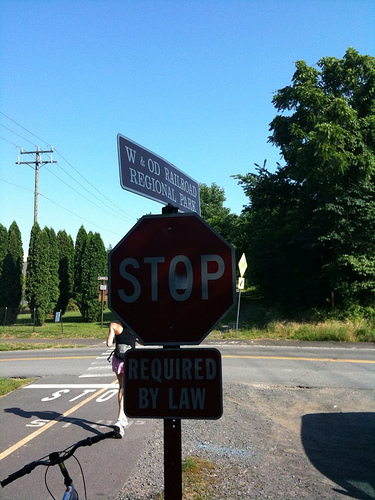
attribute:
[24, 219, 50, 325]
tree — in background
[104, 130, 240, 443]
sign — stop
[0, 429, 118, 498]
bike — blue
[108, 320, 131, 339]
top — black, tank top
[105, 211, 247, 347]
sign — red, white, stop sign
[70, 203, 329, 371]
sign — green, W & OD Railroad Regional Park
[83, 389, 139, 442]
shoe — athletic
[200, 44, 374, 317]
trees — leafy, green, on right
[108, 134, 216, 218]
rectangular sign — black, white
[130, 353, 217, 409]
writing — white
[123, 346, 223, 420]
sign — rectangular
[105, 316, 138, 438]
woman — jogging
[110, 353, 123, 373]
shorts — pink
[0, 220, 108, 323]
trees — tall, green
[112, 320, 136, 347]
tank — black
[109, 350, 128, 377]
shorts — pink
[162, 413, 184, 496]
post — green, metal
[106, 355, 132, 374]
shorts — pink